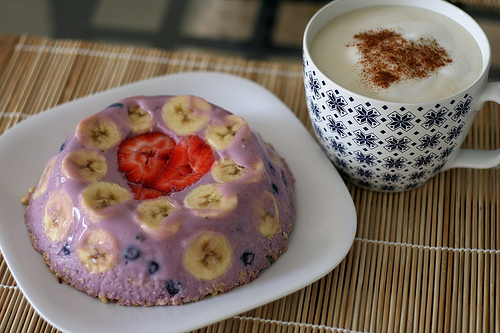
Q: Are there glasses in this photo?
A: No, there are no glasses.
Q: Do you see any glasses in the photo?
A: No, there are no glasses.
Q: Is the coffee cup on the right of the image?
A: Yes, the coffee cup is on the right of the image.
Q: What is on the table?
A: The coffee cup is on the table.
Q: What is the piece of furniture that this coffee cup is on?
A: The piece of furniture is a table.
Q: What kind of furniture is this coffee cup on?
A: The coffee cup is on the table.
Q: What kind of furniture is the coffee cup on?
A: The coffee cup is on the table.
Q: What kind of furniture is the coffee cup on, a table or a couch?
A: The coffee cup is on a table.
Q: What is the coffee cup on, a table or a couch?
A: The coffee cup is on a table.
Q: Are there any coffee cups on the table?
A: Yes, there is a coffee cup on the table.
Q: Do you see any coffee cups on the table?
A: Yes, there is a coffee cup on the table.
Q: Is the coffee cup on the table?
A: Yes, the coffee cup is on the table.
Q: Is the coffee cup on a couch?
A: No, the coffee cup is on the table.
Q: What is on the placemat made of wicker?
A: The coffee cup is on the place mat.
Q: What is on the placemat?
A: The coffee cup is on the place mat.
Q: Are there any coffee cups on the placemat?
A: Yes, there is a coffee cup on the placemat.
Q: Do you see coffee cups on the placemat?
A: Yes, there is a coffee cup on the placemat.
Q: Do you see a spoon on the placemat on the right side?
A: No, there is a coffee cup on the placemat.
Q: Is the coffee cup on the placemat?
A: Yes, the coffee cup is on the placemat.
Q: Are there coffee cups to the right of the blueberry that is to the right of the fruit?
A: Yes, there is a coffee cup to the right of the blueberry.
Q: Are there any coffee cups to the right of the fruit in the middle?
A: Yes, there is a coffee cup to the right of the blueberry.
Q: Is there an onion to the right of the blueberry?
A: No, there is a coffee cup to the right of the blueberry.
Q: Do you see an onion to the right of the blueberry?
A: No, there is a coffee cup to the right of the blueberry.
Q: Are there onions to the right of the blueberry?
A: No, there is a coffee cup to the right of the blueberry.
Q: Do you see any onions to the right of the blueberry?
A: No, there is a coffee cup to the right of the blueberry.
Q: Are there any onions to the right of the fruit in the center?
A: No, there is a coffee cup to the right of the blueberry.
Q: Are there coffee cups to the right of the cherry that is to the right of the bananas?
A: Yes, there is a coffee cup to the right of the cherry.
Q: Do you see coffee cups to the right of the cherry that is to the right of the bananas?
A: Yes, there is a coffee cup to the right of the cherry.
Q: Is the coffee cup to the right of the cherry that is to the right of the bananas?
A: Yes, the coffee cup is to the right of the cherry.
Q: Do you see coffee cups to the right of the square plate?
A: Yes, there is a coffee cup to the right of the plate.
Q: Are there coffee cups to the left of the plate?
A: No, the coffee cup is to the right of the plate.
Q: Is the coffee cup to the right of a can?
A: No, the coffee cup is to the right of the plate.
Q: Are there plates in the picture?
A: Yes, there is a plate.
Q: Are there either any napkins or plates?
A: Yes, there is a plate.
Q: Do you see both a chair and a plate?
A: No, there is a plate but no chairs.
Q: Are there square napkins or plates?
A: Yes, there is a square plate.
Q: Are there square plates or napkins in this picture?
A: Yes, there is a square plate.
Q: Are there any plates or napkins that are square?
A: Yes, the plate is square.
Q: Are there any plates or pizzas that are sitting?
A: Yes, the plate is sitting.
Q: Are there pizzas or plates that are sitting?
A: Yes, the plate is sitting.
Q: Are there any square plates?
A: Yes, there is a square plate.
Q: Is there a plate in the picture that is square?
A: Yes, there is a plate that is square.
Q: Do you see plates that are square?
A: Yes, there is a plate that is square.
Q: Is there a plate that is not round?
A: Yes, there is a square plate.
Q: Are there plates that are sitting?
A: Yes, there is a plate that is sitting.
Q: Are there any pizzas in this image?
A: No, there are no pizzas.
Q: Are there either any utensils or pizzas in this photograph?
A: No, there are no pizzas or utensils.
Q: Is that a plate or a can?
A: That is a plate.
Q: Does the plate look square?
A: Yes, the plate is square.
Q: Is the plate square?
A: Yes, the plate is square.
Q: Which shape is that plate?
A: The plate is square.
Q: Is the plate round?
A: No, the plate is square.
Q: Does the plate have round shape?
A: No, the plate is square.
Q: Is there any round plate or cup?
A: No, there is a plate but it is square.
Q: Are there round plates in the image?
A: No, there is a plate but it is square.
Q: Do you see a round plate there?
A: No, there is a plate but it is square.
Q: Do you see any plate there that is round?
A: No, there is a plate but it is square.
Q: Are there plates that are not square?
A: No, there is a plate but it is square.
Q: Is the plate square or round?
A: The plate is square.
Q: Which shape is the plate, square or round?
A: The plate is square.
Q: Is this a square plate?
A: Yes, this is a square plate.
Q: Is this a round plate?
A: No, this is a square plate.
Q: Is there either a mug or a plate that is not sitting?
A: No, there is a plate but it is sitting.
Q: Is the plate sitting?
A: Yes, the plate is sitting.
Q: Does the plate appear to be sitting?
A: Yes, the plate is sitting.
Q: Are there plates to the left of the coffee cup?
A: Yes, there is a plate to the left of the coffee cup.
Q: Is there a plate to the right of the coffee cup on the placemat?
A: No, the plate is to the left of the coffee cup.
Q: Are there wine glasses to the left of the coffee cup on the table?
A: No, there is a plate to the left of the coffee cup.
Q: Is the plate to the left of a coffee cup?
A: Yes, the plate is to the left of a coffee cup.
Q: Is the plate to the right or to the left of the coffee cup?
A: The plate is to the left of the coffee cup.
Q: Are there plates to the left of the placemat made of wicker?
A: Yes, there is a plate to the left of the placemat.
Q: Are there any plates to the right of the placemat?
A: No, the plate is to the left of the placemat.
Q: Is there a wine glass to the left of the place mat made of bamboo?
A: No, there is a plate to the left of the placemat.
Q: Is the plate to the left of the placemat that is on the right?
A: Yes, the plate is to the left of the placemat.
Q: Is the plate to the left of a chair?
A: No, the plate is to the left of the placemat.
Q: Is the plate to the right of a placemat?
A: No, the plate is to the left of a placemat.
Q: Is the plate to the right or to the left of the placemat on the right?
A: The plate is to the left of the placemat.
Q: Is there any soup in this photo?
A: No, there is no soup.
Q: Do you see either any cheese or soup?
A: No, there are no soup or cheese.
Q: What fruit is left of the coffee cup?
A: The fruit is a cherry.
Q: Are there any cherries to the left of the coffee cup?
A: Yes, there is a cherry to the left of the coffee cup.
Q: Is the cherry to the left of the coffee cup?
A: Yes, the cherry is to the left of the coffee cup.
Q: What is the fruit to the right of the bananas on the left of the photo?
A: The fruit is a cherry.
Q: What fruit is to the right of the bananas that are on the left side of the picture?
A: The fruit is a cherry.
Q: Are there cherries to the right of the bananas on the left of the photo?
A: Yes, there is a cherry to the right of the bananas.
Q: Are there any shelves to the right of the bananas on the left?
A: No, there is a cherry to the right of the bananas.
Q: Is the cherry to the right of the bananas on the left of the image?
A: Yes, the cherry is to the right of the bananas.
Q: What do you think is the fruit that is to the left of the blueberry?
A: The fruit is a cherry.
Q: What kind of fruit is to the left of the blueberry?
A: The fruit is a cherry.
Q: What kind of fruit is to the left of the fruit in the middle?
A: The fruit is a cherry.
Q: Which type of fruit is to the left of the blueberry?
A: The fruit is a cherry.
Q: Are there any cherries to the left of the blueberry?
A: Yes, there is a cherry to the left of the blueberry.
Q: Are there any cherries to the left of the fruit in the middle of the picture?
A: Yes, there is a cherry to the left of the blueberry.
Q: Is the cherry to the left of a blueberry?
A: Yes, the cherry is to the left of a blueberry.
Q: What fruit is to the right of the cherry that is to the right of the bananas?
A: The fruit is a blueberry.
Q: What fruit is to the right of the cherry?
A: The fruit is a blueberry.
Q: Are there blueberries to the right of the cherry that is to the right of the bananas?
A: Yes, there is a blueberry to the right of the cherry.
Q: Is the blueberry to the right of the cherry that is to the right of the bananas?
A: Yes, the blueberry is to the right of the cherry.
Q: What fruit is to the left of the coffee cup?
A: The fruit is a blueberry.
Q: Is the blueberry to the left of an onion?
A: No, the blueberry is to the left of the coffee cup.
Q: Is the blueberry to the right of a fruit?
A: Yes, the blueberry is to the right of a fruit.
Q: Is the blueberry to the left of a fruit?
A: No, the blueberry is to the right of a fruit.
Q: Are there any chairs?
A: No, there are no chairs.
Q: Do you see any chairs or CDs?
A: No, there are no chairs or cds.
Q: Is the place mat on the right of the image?
A: Yes, the place mat is on the right of the image.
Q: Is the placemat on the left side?
A: No, the placemat is on the right of the image.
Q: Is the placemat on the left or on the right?
A: The placemat is on the right of the image.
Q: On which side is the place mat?
A: The place mat is on the right of the image.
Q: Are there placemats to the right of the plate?
A: Yes, there is a placemat to the right of the plate.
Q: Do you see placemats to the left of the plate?
A: No, the placemat is to the right of the plate.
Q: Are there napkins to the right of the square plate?
A: No, there is a placemat to the right of the plate.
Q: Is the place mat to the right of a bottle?
A: No, the place mat is to the right of the plate.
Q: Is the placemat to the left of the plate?
A: No, the placemat is to the right of the plate.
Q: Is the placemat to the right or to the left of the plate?
A: The placemat is to the right of the plate.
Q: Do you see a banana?
A: Yes, there are bananas.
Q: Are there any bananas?
A: Yes, there are bananas.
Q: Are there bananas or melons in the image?
A: Yes, there are bananas.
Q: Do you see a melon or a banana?
A: Yes, there are bananas.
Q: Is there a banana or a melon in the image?
A: Yes, there are bananas.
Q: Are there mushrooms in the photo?
A: No, there are no mushrooms.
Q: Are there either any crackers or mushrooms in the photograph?
A: No, there are no mushrooms or crackers.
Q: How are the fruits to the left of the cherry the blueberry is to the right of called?
A: The fruits are bananas.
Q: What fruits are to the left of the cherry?
A: The fruits are bananas.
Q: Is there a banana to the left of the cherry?
A: Yes, there are bananas to the left of the cherry.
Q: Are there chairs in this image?
A: No, there are no chairs.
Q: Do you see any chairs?
A: No, there are no chairs.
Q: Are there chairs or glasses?
A: No, there are no chairs or glasses.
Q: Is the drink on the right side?
A: Yes, the drink is on the right of the image.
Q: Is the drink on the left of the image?
A: No, the drink is on the right of the image.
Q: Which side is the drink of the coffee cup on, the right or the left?
A: The drink is on the right of the image.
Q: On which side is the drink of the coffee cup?
A: The drink is on the right of the image.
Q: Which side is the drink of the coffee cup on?
A: The drink is on the right of the image.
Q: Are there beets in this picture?
A: No, there are no beets.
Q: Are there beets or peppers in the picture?
A: No, there are no beets or peppers.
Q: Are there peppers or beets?
A: No, there are no beets or peppers.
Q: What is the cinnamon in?
A: The cinnamon is in the coffee cup.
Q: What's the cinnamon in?
A: The cinnamon is in the coffee cup.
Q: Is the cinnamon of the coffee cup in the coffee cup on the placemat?
A: Yes, the cinnamon is in the coffee cup.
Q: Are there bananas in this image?
A: Yes, there is a banana.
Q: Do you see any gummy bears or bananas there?
A: Yes, there is a banana.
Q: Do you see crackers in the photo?
A: No, there are no crackers.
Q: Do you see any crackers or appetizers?
A: No, there are no crackers or appetizers.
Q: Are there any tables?
A: Yes, there is a table.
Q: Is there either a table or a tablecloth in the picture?
A: Yes, there is a table.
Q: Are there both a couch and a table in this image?
A: No, there is a table but no couches.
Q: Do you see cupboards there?
A: No, there are no cupboards.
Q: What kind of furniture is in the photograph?
A: The furniture is a table.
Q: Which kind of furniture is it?
A: The piece of furniture is a table.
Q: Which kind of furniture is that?
A: This is a table.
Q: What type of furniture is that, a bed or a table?
A: This is a table.